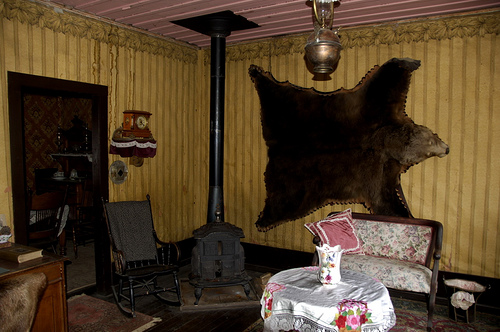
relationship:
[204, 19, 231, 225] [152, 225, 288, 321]
pipe on ground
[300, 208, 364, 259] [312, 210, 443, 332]
pillow on couch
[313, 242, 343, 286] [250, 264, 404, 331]
vase on table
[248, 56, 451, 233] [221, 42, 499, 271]
bear on wall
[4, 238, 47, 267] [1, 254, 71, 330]
book on counter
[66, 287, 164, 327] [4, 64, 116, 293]
rug front doorway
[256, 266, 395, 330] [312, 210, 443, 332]
table in front couch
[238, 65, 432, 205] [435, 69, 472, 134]
bear on wall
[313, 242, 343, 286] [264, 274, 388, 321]
vase on table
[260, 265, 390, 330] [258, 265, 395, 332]
table with tablecloth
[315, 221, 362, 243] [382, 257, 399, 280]
pillow on the seat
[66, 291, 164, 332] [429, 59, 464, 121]
rug hanging on wall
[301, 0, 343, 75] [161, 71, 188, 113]
lamp hanging on wall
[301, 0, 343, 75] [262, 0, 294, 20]
lamp hanging on ceiling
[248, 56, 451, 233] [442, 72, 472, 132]
bear hanging on wall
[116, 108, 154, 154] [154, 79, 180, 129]
clock hanging on wall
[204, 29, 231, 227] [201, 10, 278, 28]
pipe running down from ceiling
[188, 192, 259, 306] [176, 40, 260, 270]
fireplace standing in corner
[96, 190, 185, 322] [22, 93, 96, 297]
rocking chair standing near door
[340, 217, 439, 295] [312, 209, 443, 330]
fabric covering couch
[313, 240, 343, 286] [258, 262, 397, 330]
vase standing on top of table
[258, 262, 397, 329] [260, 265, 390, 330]
tablecloth covering table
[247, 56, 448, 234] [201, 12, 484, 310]
bear skin hanging on wall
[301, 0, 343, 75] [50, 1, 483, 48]
lamp hanging from ceiling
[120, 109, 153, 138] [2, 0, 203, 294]
clock standing against wall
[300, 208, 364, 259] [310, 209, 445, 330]
pillow lying on top of chair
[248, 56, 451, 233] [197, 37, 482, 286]
bear on wall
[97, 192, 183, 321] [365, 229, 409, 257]
rocking chair has pattern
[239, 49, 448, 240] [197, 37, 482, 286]
bear skin on wall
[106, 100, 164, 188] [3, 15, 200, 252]
lamp next to wall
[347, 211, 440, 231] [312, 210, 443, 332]
trim on couch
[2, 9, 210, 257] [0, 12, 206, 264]
wallpaper on wall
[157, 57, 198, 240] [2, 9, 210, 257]
stripes on wallpaper